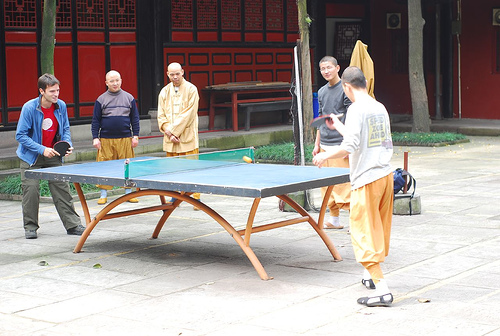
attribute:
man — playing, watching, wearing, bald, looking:
[17, 56, 409, 312]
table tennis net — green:
[127, 147, 258, 183]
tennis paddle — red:
[53, 143, 71, 158]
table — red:
[201, 74, 291, 132]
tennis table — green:
[30, 140, 352, 261]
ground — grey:
[1, 131, 498, 311]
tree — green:
[0, 3, 431, 192]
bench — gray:
[226, 99, 295, 124]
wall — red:
[5, 2, 498, 125]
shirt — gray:
[318, 81, 346, 142]